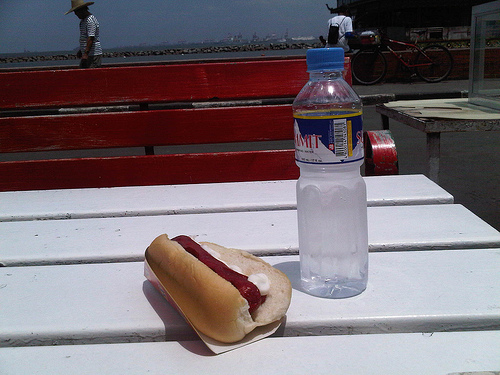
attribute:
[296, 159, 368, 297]
water — cold, clear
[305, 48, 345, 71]
cap — blue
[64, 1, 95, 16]
cowboy hat — brown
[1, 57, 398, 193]
bench — red, metal, dark red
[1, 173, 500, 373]
table — slatted, outdoors, white, wooden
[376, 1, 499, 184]
chair — white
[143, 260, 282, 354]
paper container — disposable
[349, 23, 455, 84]
bike — red, black, resting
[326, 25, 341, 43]
backpack — black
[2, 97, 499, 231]
sidewalk — asphalt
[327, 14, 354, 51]
shirt — white